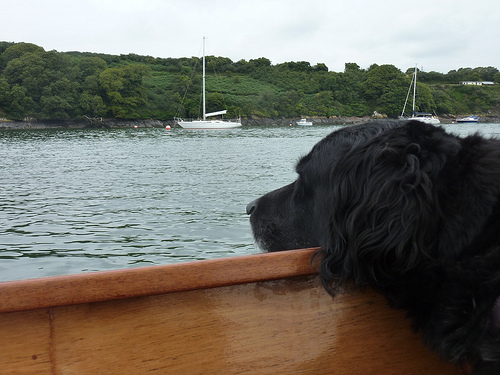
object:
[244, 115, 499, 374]
dog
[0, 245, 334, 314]
ledge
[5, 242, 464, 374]
boat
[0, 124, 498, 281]
water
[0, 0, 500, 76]
sky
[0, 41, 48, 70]
trees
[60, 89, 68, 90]
leaves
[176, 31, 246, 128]
boat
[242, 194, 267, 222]
nose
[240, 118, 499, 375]
fur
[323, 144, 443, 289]
ears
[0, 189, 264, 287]
ripples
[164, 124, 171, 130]
buoys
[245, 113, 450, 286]
head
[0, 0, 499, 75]
clouds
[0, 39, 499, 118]
forest